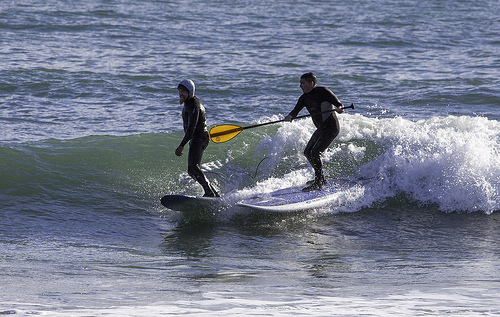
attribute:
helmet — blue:
[176, 77, 208, 99]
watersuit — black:
[296, 91, 346, 163]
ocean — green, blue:
[91, 14, 266, 113]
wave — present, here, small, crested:
[256, 111, 494, 197]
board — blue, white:
[158, 125, 351, 232]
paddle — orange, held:
[207, 117, 259, 170]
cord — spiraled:
[248, 158, 286, 203]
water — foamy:
[386, 116, 460, 206]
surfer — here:
[152, 76, 235, 203]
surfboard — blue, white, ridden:
[160, 165, 377, 221]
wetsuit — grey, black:
[292, 91, 349, 214]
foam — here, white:
[398, 136, 498, 206]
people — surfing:
[166, 69, 349, 203]